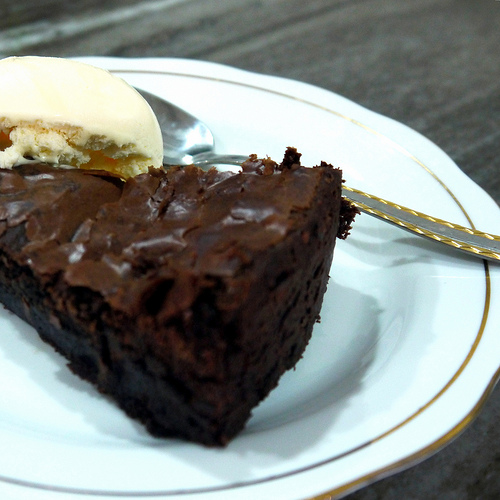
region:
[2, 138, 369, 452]
this is a piece of cake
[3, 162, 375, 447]
this is a cake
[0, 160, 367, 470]
this is a chocolate cake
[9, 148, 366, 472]
this is a brownie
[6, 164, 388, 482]
a chocolate brownie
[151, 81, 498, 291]
this is the spoon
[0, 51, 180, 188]
this is a scoop of ice cream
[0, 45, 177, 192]
a scoop of vanilla ice cream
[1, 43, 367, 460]
the cake is being served a la mode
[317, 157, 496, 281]
the handle of the spoon is gold and silver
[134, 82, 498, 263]
Silver spoon with gold detail around edge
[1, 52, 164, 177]
Scoop of vanila ice cream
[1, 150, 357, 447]
Triangular slice of chocolate cake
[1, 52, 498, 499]
Round white plate with scalloped edges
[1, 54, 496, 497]
Round white plate with gold details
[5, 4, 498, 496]
Plate sitting on gray table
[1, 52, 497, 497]
Cake and ice cream on plate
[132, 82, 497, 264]
Gold triangular design on spoon handle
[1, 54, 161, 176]
Slightly melted scoop of vanila ice cream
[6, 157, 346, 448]
Dense piece of chocolate baked dessert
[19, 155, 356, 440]
piece of chocolate cake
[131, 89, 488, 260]
spoon with gold trim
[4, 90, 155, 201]
vanilla ice cream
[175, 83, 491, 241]
part of a white plate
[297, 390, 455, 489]
white plate trimmed in gold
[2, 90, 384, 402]
food on a plate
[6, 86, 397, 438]
a plate of desert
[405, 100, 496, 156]
part of a table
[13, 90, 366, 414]
some good stuff to eat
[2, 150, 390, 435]
brown cake on a plate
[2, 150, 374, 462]
chocolate brownie on a plate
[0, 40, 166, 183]
scoop of vanilla ice cream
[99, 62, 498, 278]
silver spoon with gold trim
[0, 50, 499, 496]
white plate with gold trim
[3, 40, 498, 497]
brownie ice cream and spoon on a plate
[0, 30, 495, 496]
delicious looking chocolate dessert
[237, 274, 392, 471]
shadow of the brownie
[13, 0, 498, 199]
gray table top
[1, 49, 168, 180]
scoop of a frozen dairy item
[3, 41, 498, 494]
the plate is circular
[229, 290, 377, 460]
the shadow of the brownie on the plate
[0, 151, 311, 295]
the crust of the brownie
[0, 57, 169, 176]
a lump of vanilla icecream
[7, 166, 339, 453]
a brownie on a plate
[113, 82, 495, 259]
a spoon on the plate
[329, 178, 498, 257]
gold on the spoon handle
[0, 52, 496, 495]
a white plate on the table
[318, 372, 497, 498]
gold around the edge of the plate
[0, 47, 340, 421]
a brownie with vanilla icecream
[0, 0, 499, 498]
a gray table under the plate